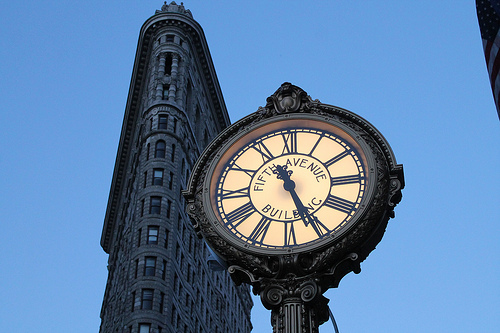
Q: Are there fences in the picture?
A: No, there are no fences.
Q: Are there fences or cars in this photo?
A: No, there are no fences or cars.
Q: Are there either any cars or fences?
A: No, there are no fences or cars.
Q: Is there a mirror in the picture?
A: No, there are no mirrors.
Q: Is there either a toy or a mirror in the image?
A: No, there are no mirrors or toys.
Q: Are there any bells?
A: No, there are no bells.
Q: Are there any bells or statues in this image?
A: No, there are no bells or statues.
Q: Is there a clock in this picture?
A: Yes, there is a clock.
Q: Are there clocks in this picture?
A: Yes, there is a clock.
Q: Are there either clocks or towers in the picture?
A: Yes, there is a clock.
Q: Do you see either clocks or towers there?
A: Yes, there is a clock.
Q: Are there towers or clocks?
A: Yes, there is a clock.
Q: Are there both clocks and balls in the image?
A: No, there is a clock but no balls.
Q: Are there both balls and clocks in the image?
A: No, there is a clock but no balls.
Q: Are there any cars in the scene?
A: No, there are no cars.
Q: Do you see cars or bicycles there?
A: No, there are no cars or bicycles.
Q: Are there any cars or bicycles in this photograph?
A: No, there are no cars or bicycles.